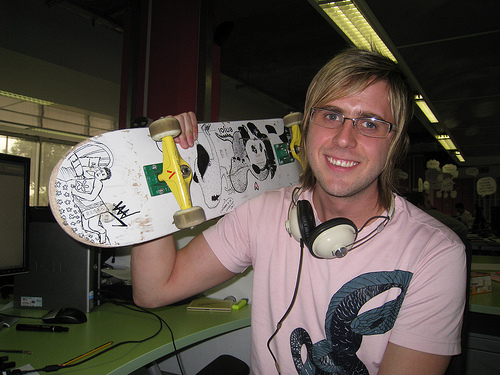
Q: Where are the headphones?
A: Around the man's neck.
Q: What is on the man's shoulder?
A: Skateboard?.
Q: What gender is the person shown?
A: Male.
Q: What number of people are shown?
A: 1.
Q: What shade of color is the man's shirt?
A: Pink.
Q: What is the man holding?
A: Skateboard.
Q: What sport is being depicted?
A: Skateboarding.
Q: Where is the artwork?
A: Bottom of the skateboard.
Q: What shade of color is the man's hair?
A: Blonde.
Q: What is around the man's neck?
A: Headphones.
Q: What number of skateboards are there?
A: 1.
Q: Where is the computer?
A: ON the desk.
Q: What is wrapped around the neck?
A: Headphones.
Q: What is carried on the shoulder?
A: Skateboard.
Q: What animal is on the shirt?
A: A snake.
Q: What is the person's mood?
A: Happy.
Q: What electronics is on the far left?
A: Computer monitor.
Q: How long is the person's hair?
A: Shoulder length.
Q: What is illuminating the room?
A: Overhead lights.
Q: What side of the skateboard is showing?
A: The bottom.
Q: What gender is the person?
A: Male.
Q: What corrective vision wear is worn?
A: Glasses.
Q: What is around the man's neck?
A: Headphones.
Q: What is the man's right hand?
A: A skateboard.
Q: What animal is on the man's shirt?
A: A snake.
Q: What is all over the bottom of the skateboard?
A: Graffiti.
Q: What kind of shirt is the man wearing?
A: A pink t-shirt.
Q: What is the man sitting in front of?
A: A desk.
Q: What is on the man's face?
A: Eyeglasses.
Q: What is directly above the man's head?
A: Lights.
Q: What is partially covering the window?
A: Blinds.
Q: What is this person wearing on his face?
A: Glasses.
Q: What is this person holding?
A: Skateboard.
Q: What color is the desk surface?
A: Green.